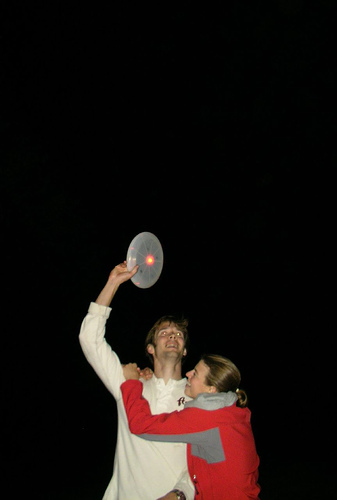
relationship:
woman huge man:
[120, 351, 261, 497] [76, 257, 204, 500]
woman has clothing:
[120, 351, 261, 497] [119, 377, 262, 499]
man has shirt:
[76, 257, 204, 500] [79, 301, 200, 497]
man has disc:
[76, 257, 204, 500] [125, 230, 164, 289]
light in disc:
[146, 253, 154, 265] [125, 230, 164, 289]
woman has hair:
[120, 351, 261, 497] [204, 358, 251, 402]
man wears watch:
[76, 257, 204, 500] [171, 486, 183, 500]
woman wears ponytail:
[120, 351, 261, 497] [236, 389, 250, 410]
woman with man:
[120, 351, 261, 497] [76, 257, 204, 500]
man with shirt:
[77, 257, 203, 498] [75, 298, 192, 498]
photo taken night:
[3, 2, 336, 496] [5, 4, 335, 495]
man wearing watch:
[77, 257, 203, 498] [158, 478, 183, 498]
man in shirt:
[76, 257, 204, 500] [107, 362, 190, 498]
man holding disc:
[76, 257, 204, 500] [123, 230, 162, 285]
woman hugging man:
[120, 352, 265, 500] [111, 309, 188, 499]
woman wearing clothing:
[120, 352, 265, 500] [119, 377, 262, 499]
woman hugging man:
[120, 352, 265, 500] [139, 312, 191, 414]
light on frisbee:
[146, 255, 152, 264] [124, 230, 166, 291]